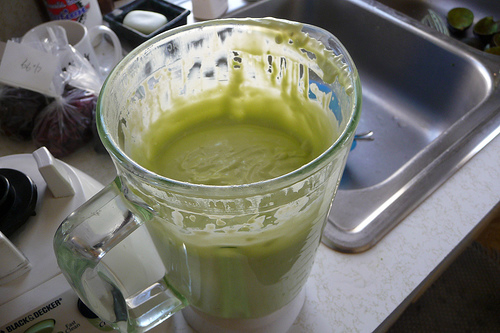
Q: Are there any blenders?
A: Yes, there is a blender.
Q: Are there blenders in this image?
A: Yes, there is a blender.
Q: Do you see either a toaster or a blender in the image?
A: Yes, there is a blender.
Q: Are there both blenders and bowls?
A: No, there is a blender but no bowls.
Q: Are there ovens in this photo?
A: No, there are no ovens.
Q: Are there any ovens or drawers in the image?
A: No, there are no ovens or drawers.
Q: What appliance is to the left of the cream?
A: The appliance is a blender.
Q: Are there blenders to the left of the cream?
A: Yes, there is a blender to the left of the cream.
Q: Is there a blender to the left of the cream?
A: Yes, there is a blender to the left of the cream.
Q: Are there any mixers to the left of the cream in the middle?
A: No, there is a blender to the left of the cream.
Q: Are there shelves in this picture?
A: No, there are no shelves.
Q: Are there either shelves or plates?
A: No, there are no shelves or plates.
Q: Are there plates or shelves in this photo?
A: No, there are no shelves or plates.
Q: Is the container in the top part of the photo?
A: Yes, the container is in the top of the image.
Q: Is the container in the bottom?
A: No, the container is in the top of the image.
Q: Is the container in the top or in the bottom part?
A: The container is in the top of the image.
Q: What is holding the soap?
A: The container is holding the soap.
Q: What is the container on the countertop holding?
A: The container is holding the soap.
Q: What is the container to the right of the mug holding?
A: The container is holding the soap.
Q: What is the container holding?
A: The container is holding the soap.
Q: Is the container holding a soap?
A: Yes, the container is holding a soap.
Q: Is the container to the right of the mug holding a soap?
A: Yes, the container is holding a soap.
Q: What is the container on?
A: The container is on the counter top.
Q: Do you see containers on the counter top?
A: Yes, there is a container on the counter top.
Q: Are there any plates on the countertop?
A: No, there is a container on the countertop.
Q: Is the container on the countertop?
A: Yes, the container is on the countertop.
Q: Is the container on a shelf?
A: No, the container is on the countertop.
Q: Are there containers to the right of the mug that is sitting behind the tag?
A: Yes, there is a container to the right of the mug.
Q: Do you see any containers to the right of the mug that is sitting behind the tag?
A: Yes, there is a container to the right of the mug.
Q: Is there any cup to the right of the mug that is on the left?
A: No, there is a container to the right of the mug.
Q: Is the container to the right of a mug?
A: Yes, the container is to the right of a mug.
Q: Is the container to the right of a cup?
A: No, the container is to the right of a mug.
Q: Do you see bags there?
A: Yes, there is a bag.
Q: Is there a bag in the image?
A: Yes, there is a bag.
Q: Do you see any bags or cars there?
A: Yes, there is a bag.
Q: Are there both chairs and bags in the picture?
A: No, there is a bag but no chairs.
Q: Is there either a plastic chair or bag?
A: Yes, there is a plastic bag.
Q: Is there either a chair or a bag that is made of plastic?
A: Yes, the bag is made of plastic.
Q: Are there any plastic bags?
A: Yes, there is a bag that is made of plastic.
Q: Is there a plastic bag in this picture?
A: Yes, there is a bag that is made of plastic.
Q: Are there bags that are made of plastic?
A: Yes, there is a bag that is made of plastic.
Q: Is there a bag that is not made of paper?
A: Yes, there is a bag that is made of plastic.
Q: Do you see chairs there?
A: No, there are no chairs.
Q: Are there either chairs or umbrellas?
A: No, there are no chairs or umbrellas.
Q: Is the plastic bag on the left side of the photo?
A: Yes, the bag is on the left of the image.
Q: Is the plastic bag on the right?
A: No, the bag is on the left of the image.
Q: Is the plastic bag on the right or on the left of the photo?
A: The bag is on the left of the image.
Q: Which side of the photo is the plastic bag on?
A: The bag is on the left of the image.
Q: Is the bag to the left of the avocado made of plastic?
A: Yes, the bag is made of plastic.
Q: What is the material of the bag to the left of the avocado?
A: The bag is made of plastic.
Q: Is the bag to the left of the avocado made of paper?
A: No, the bag is made of plastic.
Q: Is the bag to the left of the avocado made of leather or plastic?
A: The bag is made of plastic.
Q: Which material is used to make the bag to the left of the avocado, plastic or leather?
A: The bag is made of plastic.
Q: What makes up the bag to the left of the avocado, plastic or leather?
A: The bag is made of plastic.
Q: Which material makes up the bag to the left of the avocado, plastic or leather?
A: The bag is made of plastic.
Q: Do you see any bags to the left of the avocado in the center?
A: Yes, there is a bag to the left of the avocado.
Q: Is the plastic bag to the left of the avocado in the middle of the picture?
A: Yes, the bag is to the left of the avocado.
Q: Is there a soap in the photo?
A: Yes, there is a soap.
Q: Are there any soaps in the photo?
A: Yes, there is a soap.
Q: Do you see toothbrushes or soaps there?
A: Yes, there is a soap.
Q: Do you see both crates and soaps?
A: No, there is a soap but no crates.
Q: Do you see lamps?
A: No, there are no lamps.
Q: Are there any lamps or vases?
A: No, there are no lamps or vases.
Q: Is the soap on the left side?
A: Yes, the soap is on the left of the image.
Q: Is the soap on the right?
A: No, the soap is on the left of the image.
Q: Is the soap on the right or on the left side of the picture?
A: The soap is on the left of the image.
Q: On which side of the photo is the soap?
A: The soap is on the left of the image.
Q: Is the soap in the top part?
A: Yes, the soap is in the top of the image.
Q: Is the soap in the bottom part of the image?
A: No, the soap is in the top of the image.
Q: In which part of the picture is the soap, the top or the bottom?
A: The soap is in the top of the image.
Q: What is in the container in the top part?
A: The soap is in the container.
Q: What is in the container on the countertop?
A: The soap is in the container.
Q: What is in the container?
A: The soap is in the container.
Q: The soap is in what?
A: The soap is in the container.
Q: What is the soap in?
A: The soap is in the container.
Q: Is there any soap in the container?
A: Yes, there is a soap in the container.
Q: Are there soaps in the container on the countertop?
A: Yes, there is a soap in the container.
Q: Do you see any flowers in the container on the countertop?
A: No, there is a soap in the container.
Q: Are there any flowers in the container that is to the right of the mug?
A: No, there is a soap in the container.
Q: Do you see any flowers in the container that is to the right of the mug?
A: No, there is a soap in the container.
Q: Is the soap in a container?
A: Yes, the soap is in a container.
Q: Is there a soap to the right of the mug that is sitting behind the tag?
A: Yes, there is a soap to the right of the mug.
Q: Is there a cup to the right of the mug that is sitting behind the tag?
A: No, there is a soap to the right of the mug.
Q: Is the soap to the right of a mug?
A: Yes, the soap is to the right of a mug.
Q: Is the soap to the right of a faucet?
A: No, the soap is to the right of a mug.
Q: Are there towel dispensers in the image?
A: No, there are no towel dispensers.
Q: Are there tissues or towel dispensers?
A: No, there are no towel dispensers or tissues.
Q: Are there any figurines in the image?
A: No, there are no figurines.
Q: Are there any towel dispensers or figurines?
A: No, there are no figurines or towel dispensers.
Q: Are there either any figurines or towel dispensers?
A: No, there are no figurines or towel dispensers.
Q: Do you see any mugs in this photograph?
A: Yes, there is a mug.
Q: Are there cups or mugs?
A: Yes, there is a mug.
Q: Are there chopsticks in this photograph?
A: No, there are no chopsticks.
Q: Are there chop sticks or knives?
A: No, there are no chop sticks or knives.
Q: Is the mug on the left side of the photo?
A: Yes, the mug is on the left of the image.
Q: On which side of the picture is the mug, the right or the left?
A: The mug is on the left of the image.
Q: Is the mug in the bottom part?
A: No, the mug is in the top of the image.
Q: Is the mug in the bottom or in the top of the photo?
A: The mug is in the top of the image.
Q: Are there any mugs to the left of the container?
A: Yes, there is a mug to the left of the container.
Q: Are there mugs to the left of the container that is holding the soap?
A: Yes, there is a mug to the left of the container.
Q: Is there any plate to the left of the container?
A: No, there is a mug to the left of the container.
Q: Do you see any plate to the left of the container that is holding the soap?
A: No, there is a mug to the left of the container.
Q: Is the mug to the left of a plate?
A: No, the mug is to the left of the container.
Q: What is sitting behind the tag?
A: The mug is sitting behind the tag.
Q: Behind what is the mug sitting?
A: The mug is sitting behind the tag.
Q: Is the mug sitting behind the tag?
A: Yes, the mug is sitting behind the tag.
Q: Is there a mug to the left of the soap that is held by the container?
A: Yes, there is a mug to the left of the soap.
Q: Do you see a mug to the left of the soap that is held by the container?
A: Yes, there is a mug to the left of the soap.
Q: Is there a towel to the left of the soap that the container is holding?
A: No, there is a mug to the left of the soap.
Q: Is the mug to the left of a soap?
A: Yes, the mug is to the left of a soap.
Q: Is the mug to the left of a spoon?
A: No, the mug is to the left of a soap.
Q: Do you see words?
A: Yes, there are words.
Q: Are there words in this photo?
A: Yes, there are words.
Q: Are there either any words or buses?
A: Yes, there are words.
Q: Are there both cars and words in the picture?
A: No, there are words but no cars.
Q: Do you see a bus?
A: No, there are no buses.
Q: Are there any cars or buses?
A: No, there are no buses or cars.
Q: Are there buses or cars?
A: No, there are no buses or cars.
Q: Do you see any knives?
A: No, there are no knives.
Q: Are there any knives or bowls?
A: No, there are no knives or bowls.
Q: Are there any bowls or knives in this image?
A: No, there are no knives or bowls.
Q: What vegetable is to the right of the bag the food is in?
A: The vegetable is an avocado.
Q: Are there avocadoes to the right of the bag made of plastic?
A: Yes, there is an avocado to the right of the bag.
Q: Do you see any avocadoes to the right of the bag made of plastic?
A: Yes, there is an avocado to the right of the bag.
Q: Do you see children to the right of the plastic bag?
A: No, there is an avocado to the right of the bag.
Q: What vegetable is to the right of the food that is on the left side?
A: The vegetable is an avocado.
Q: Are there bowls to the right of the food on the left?
A: No, there is an avocado to the right of the food.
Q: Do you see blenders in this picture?
A: Yes, there is a blender.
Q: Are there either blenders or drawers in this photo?
A: Yes, there is a blender.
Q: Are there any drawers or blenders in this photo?
A: Yes, there is a blender.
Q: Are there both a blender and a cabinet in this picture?
A: No, there is a blender but no cabinets.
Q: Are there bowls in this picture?
A: No, there are no bowls.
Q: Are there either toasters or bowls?
A: No, there are no bowls or toasters.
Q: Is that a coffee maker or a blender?
A: That is a blender.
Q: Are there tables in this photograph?
A: Yes, there is a table.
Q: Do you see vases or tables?
A: Yes, there is a table.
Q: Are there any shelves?
A: No, there are no shelves.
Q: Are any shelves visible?
A: No, there are no shelves.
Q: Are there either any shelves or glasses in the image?
A: No, there are no shelves or glasses.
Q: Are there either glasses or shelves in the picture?
A: No, there are no shelves or glasses.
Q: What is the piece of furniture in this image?
A: The piece of furniture is a table.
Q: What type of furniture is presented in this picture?
A: The furniture is a table.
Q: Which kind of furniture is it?
A: The piece of furniture is a table.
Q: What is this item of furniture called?
A: This is a table.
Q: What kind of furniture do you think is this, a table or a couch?
A: This is a table.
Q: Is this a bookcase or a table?
A: This is a table.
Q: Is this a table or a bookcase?
A: This is a table.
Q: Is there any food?
A: Yes, there is food.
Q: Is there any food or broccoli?
A: Yes, there is food.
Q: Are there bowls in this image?
A: No, there are no bowls.